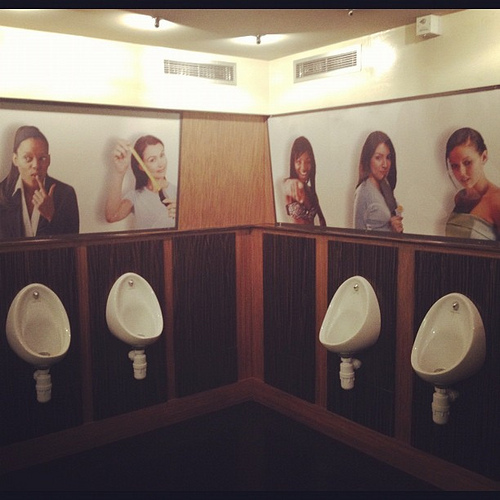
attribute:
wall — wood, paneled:
[2, 223, 498, 498]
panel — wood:
[256, 231, 315, 408]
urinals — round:
[20, 248, 446, 416]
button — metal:
[30, 287, 38, 299]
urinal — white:
[3, 279, 75, 405]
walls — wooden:
[256, 224, 498, 498]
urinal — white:
[74, 259, 184, 397]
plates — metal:
[159, 45, 371, 110]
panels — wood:
[3, 230, 498, 482]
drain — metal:
[433, 366, 445, 373]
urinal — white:
[364, 244, 490, 456]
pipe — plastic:
[418, 378, 474, 444]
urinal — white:
[3, 279, 73, 371]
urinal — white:
[104, 267, 167, 348]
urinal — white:
[315, 270, 383, 356]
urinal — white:
[409, 291, 488, 395]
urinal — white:
[7, 278, 73, 399]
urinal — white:
[103, 270, 166, 380]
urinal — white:
[318, 271, 386, 392]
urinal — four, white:
[408, 290, 490, 425]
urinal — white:
[100, 265, 171, 382]